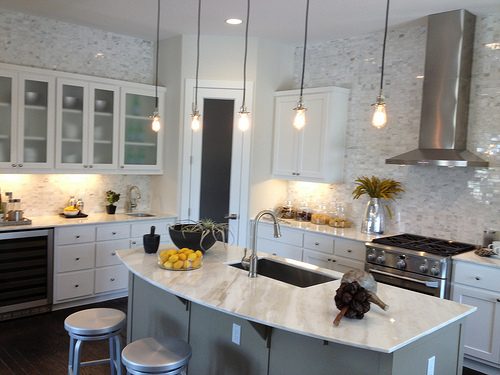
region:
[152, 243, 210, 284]
YELLOW LEMONS IN BOWL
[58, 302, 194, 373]
two silver stools under counter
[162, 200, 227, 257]
aloe vera plant in black bowl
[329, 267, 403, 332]
fruit on the counter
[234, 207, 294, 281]
silver faucet for sink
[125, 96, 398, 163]
five lights over a bar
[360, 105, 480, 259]
silver exhaust fan over stove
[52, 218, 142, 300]
white cupboards with silver handles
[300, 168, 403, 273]
green plant in silver pitcher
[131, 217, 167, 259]
black bowl for grinding powder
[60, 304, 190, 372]
two silver round stool tops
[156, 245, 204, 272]
glass bowl full of yellow lemons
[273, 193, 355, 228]
four glass canisters on counter top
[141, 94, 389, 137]
five hanging bare bulb lights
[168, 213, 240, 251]
plant in a large black bowl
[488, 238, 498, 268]
two white cup handles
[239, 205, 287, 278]
silver tall kichen faucet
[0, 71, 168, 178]
glass door cabinets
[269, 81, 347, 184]
white two door wood cabinet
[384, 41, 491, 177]
stainless steel stove hood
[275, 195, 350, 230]
Glass canisters on the countertop.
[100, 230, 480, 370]
A kitchen island with a sink.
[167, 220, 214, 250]
A large dark bowl.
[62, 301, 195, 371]
Silver round barstools.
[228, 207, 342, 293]
A kitchen sink.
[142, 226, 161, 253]
A mortar and pestle.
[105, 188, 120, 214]
A small houseplant.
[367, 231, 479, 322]
A stainless steel oven set.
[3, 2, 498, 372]
A kitchen.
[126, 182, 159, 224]
A small sink.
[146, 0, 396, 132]
The hanging light fixtures are lit up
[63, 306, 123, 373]
The top of a grey bar stool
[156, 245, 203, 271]
A glass dish full of lemons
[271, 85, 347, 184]
A white wood wall cabinet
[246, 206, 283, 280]
A chrome faucet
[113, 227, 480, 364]
A white and grey marble countertop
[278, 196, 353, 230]
Four glass cookie jars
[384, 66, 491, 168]
A metal stove hood vent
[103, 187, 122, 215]
A small plant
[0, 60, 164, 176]
Wall cabinets with glass in the doors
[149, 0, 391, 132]
light fixtures hanging from the ceiling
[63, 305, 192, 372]
two metal stools in a kitchen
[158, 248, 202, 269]
a bunch of lemons in a plastic bowl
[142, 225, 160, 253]
a mortar and pestle on a counter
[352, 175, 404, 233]
a green plant in a silver pot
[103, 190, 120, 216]
small green plant in a black pot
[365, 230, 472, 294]
a silver mordern stove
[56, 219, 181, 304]
white drawers in a kitchen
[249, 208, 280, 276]
a silver faucet on a kitchen island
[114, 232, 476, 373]
a kitchen island